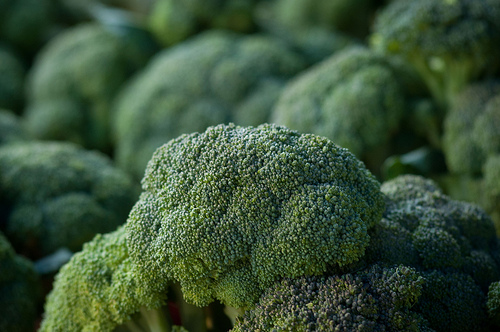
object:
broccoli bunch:
[36, 121, 500, 332]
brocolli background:
[0, 0, 500, 332]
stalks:
[137, 298, 172, 332]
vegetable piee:
[0, 43, 29, 117]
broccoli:
[18, 20, 156, 163]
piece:
[0, 137, 145, 261]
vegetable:
[122, 123, 386, 332]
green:
[174, 63, 184, 76]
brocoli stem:
[167, 283, 209, 332]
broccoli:
[0, 232, 51, 332]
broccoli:
[367, 0, 500, 116]